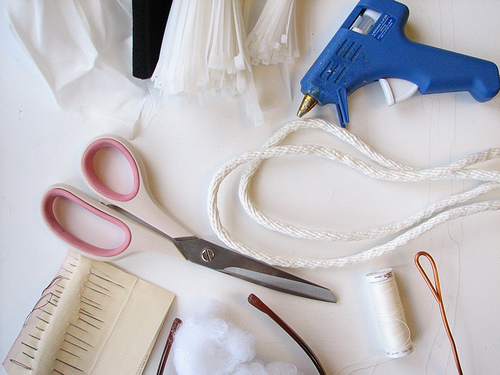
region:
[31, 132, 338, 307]
scissors on table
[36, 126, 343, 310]
pink and white scissors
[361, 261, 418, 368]
white thread on table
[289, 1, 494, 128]
blue glue gun on table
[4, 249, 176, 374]
sewing needles on table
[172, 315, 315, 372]
white cotton on table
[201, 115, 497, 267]
white rope on table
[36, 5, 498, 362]
craft supplies on table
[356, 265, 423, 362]
spool of sewing thread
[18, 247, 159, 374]
silver sewing needles on paper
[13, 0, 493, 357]
Items used in arts and crafts.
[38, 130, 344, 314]
A pair of pink handled scissors.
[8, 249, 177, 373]
Pack of different size needles.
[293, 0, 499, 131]
A blue glue gun.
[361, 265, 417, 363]
A roll of white thread.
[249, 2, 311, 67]
A bunch of small plastic ties.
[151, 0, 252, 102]
A bunch of large plastic ties.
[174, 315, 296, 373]
A ball of white cotton.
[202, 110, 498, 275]
A length of white cord.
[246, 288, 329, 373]
Edge of eyeglass leg.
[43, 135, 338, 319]
A pair of scissors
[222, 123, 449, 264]
A wick in the photo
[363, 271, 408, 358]
Thread in the photo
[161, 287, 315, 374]
Eyeglasses in the photo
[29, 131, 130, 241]
Pink handles of scissors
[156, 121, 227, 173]
A white surface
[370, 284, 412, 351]
A white thread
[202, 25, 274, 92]
White cloth in the photo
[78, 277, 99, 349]
Needles in the photo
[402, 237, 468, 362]
Wire in the photo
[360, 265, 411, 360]
a spool of white thread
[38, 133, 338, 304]
a pair of scissors with pink grips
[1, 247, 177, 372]
a package of sewing needles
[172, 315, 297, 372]
a ball of cotton stuffing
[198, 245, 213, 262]
screw holding together a pair of scissors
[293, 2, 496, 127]
a blue hot glue gun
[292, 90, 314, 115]
tip of hot glue gun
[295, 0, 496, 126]
blue hot glue gun with white trigger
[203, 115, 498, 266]
two pieces of white rope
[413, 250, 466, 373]
a piece of copper wire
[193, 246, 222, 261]
small silver screw in scissors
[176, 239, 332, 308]
silver and black blades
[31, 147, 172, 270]
pink handle on scissors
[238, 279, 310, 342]
long red frame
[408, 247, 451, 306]
gold yarn needle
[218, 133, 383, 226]
large piece of white twine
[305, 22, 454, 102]
large blue glue gun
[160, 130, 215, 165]
white surface under objects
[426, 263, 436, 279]
eye in gold yarn needle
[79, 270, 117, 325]
row of silver needles on cloth